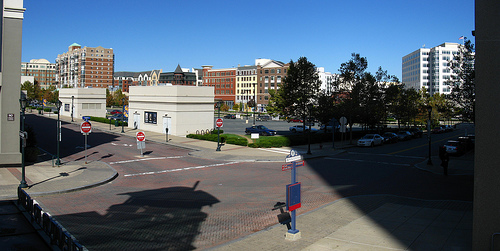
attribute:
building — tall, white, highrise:
[396, 35, 472, 102]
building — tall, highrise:
[43, 41, 112, 89]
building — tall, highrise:
[23, 52, 60, 96]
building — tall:
[201, 62, 307, 109]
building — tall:
[144, 60, 198, 84]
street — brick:
[41, 115, 441, 238]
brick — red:
[62, 140, 472, 241]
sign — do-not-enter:
[67, 111, 107, 154]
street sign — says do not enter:
[127, 107, 159, 175]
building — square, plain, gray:
[112, 82, 221, 133]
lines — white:
[120, 154, 236, 178]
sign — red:
[78, 122, 97, 165]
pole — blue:
[286, 151, 313, 234]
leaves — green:
[283, 86, 320, 114]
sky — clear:
[127, 17, 276, 78]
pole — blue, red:
[276, 145, 304, 238]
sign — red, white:
[129, 133, 148, 154]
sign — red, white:
[73, 114, 98, 164]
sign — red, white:
[218, 112, 224, 135]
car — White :
[207, 112, 309, 160]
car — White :
[224, 104, 341, 162]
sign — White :
[239, 76, 339, 167]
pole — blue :
[283, 106, 321, 179]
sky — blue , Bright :
[48, 5, 434, 101]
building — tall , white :
[385, 26, 469, 143]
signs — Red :
[87, 101, 234, 154]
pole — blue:
[258, 170, 324, 235]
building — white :
[259, 29, 376, 181]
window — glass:
[442, 47, 452, 54]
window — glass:
[423, 63, 431, 68]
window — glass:
[444, 84, 452, 92]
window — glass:
[419, 55, 428, 61]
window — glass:
[411, 70, 416, 72]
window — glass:
[431, 79, 439, 88]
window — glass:
[271, 79, 283, 86]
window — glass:
[272, 80, 283, 88]